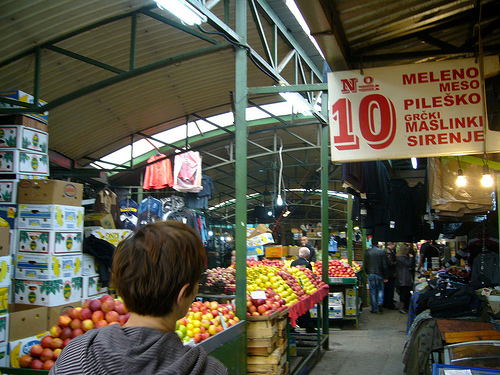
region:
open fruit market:
[2, 1, 497, 372]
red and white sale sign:
[325, 58, 485, 158]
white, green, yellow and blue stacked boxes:
[15, 178, 85, 298]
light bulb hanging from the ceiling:
[275, 137, 285, 207]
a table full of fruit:
[203, 257, 330, 319]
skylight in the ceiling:
[88, 83, 309, 171]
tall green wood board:
[235, 43, 247, 318]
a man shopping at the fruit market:
[398, 297, 448, 372]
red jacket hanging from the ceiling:
[142, 151, 172, 188]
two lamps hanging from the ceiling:
[452, 98, 493, 190]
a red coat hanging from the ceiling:
[140, 150, 171, 191]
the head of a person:
[106, 220, 203, 320]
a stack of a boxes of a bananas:
[5, 115, 90, 305]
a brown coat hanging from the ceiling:
[91, 180, 121, 216]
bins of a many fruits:
[49, 250, 360, 350]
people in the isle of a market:
[363, 230, 418, 312]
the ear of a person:
[173, 280, 193, 306]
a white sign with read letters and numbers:
[323, 59, 493, 164]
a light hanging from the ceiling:
[273, 148, 287, 208]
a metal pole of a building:
[226, 46, 251, 373]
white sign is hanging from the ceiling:
[326, 60, 492, 166]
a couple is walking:
[360, 236, 416, 315]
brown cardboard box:
[14, 178, 84, 205]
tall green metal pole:
[235, 1, 255, 373]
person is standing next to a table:
[31, 221, 230, 373]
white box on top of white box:
[14, 205, 84, 233]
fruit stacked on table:
[16, 295, 132, 366]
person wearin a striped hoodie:
[43, 324, 229, 374]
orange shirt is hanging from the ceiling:
[141, 154, 173, 189]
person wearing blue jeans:
[366, 274, 388, 314]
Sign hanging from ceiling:
[322, 63, 499, 153]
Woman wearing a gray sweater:
[51, 213, 241, 373]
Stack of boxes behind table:
[0, 113, 122, 368]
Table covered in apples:
[204, 256, 331, 318]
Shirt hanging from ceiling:
[169, 147, 209, 198]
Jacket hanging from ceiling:
[134, 142, 181, 192]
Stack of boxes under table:
[240, 315, 296, 374]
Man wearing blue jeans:
[362, 238, 389, 313]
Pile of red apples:
[15, 292, 177, 373]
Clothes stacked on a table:
[412, 261, 498, 326]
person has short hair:
[64, 212, 235, 370]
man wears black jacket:
[360, 230, 393, 316]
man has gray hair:
[291, 240, 316, 272]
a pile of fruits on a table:
[214, 248, 334, 319]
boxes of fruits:
[0, 82, 96, 302]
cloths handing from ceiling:
[123, 145, 220, 224]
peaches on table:
[246, 288, 288, 317]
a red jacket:
[136, 145, 173, 192]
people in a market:
[313, 200, 453, 312]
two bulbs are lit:
[447, 160, 494, 199]